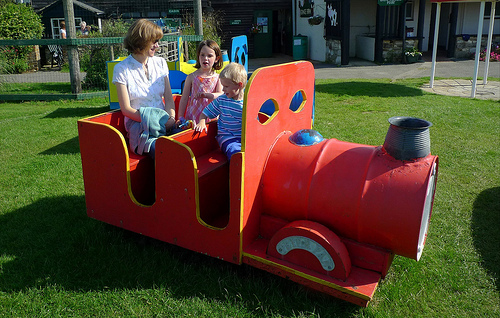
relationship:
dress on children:
[190, 70, 220, 112] [175, 39, 224, 127]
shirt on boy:
[201, 100, 242, 139] [193, 61, 258, 159]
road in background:
[13, 56, 465, 91] [20, 12, 476, 91]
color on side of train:
[288, 267, 340, 291] [65, 56, 441, 310]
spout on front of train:
[380, 112, 434, 159] [65, 56, 441, 310]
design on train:
[254, 87, 308, 131] [65, 56, 441, 310]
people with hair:
[111, 17, 185, 157] [122, 18, 163, 56]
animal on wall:
[325, 6, 339, 27] [297, 2, 467, 56]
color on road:
[354, 60, 420, 77] [0, 61, 465, 83]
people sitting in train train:
[111, 17, 185, 157] [65, 56, 441, 310]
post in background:
[8, 34, 61, 52] [20, 7, 483, 98]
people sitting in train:
[111, 17, 185, 157] [65, 56, 441, 310]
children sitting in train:
[178, 36, 247, 136] [65, 56, 441, 310]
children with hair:
[175, 39, 224, 127] [192, 39, 222, 68]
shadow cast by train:
[8, 196, 358, 306] [65, 56, 441, 310]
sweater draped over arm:
[134, 106, 169, 155] [110, 69, 163, 125]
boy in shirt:
[193, 60, 240, 150] [203, 94, 241, 142]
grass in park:
[18, 95, 64, 202] [20, 8, 455, 295]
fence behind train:
[5, 33, 105, 90] [65, 56, 441, 310]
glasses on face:
[149, 32, 165, 43] [129, 10, 164, 61]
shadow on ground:
[0, 195, 358, 318] [5, 177, 483, 316]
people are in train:
[108, 17, 238, 147] [75, 71, 435, 296]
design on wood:
[257, 88, 308, 126] [246, 58, 316, 199]